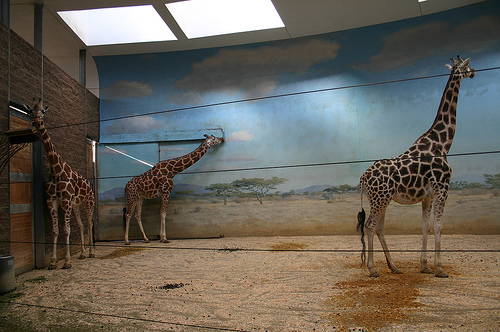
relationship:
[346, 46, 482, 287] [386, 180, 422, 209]
giraffe has stomach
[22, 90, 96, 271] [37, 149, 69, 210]
giraffe has chest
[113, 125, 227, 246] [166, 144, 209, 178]
giraffe has neck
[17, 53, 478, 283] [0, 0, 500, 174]
giraffes in enclosure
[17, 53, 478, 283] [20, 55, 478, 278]
giraffes in giraffes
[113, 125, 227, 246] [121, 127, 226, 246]
giraffe in giraffe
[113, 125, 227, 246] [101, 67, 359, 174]
giraffe in sky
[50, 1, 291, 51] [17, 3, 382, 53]
lights on ceiling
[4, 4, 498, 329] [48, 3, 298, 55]
enclosure has skylight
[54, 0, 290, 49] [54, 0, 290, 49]
lights for lights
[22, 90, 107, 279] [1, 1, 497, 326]
giraffe faces camera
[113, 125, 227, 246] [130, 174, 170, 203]
giraffe has coat